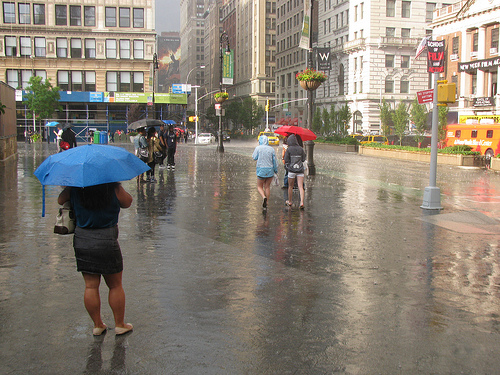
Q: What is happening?
A: Raining.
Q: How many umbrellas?
A: 4.